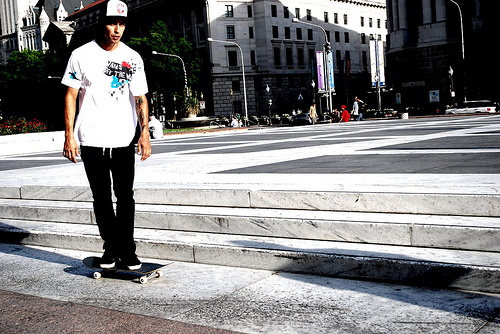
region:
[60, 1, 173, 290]
A guy is skateboarding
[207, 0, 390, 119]
The side of a white building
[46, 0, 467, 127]
A row of street lamps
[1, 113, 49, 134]
A bunch of red flowers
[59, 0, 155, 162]
Guy is wearing a white shirt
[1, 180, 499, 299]
A set of steps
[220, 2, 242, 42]
Two windows on a building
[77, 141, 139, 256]
A pair of black pants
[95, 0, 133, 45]
Hat on guy's head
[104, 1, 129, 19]
white top of hat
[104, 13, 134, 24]
black brim of hat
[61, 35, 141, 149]
white t shirt on guy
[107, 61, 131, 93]
graphic on top of shirt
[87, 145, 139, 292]
black pants on man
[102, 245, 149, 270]
black and white shoes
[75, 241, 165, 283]
black top to board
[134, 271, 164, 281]
white wheels on bottom of board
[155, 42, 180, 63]
tall silver street light pole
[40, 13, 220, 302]
this is a man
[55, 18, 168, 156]
white shirt on man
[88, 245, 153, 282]
man wearing black shoes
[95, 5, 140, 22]
man wearing a white hat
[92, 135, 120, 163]
drawstring on black pants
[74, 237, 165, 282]
this is a skateboard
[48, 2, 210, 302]
man riding a skateboard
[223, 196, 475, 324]
this is a shadow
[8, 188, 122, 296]
shadow of the skateboarder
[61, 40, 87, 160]
the arm of the skateboarder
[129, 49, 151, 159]
the arm of the skateboarder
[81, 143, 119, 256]
the leg of the skateboarder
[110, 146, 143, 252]
the leg of the skateboarder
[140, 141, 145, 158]
the long finger on a hand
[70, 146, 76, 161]
the long finger on a hand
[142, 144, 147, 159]
the long finger on a hand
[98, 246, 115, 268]
the black and white shoe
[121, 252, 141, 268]
the black and white shoe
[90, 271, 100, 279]
the white wheel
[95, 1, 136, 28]
a man with a white and black hat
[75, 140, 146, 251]
a man with black pants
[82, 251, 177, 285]
a black skate board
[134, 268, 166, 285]
the tire of a skateboard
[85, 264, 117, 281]
the tire of a skateboard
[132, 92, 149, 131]
a tattoo on a man's arm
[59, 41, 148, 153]
a man with a white shirt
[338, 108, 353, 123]
a person with a red shirt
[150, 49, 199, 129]
a light pole in the background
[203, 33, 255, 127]
a light pole in the background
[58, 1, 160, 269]
man standing on black skateboard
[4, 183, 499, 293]
large gray pavement stairs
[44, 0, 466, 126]
a bunch of gray lampposts in sidewalk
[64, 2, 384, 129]
big building in the corner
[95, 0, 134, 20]
a black and white baseball cap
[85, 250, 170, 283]
a black skateboard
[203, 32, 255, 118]
a tall outdoor light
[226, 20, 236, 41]
a window of a building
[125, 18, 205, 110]
a tall green tree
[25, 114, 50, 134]
a red and green bush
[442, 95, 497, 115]
the side of an suv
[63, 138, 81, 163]
the hand of a man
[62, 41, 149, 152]
a man's short sleeve shirt